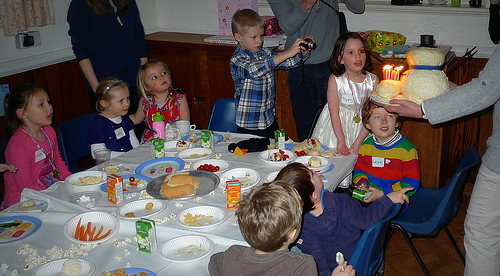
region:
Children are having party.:
[6, 33, 438, 258]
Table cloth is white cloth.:
[55, 163, 242, 260]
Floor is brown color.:
[389, 230, 476, 273]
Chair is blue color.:
[360, 153, 465, 271]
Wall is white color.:
[144, 11, 228, 36]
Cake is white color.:
[376, 37, 453, 108]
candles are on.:
[371, 56, 416, 120]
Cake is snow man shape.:
[402, 23, 464, 105]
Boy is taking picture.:
[226, 16, 321, 129]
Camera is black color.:
[288, 39, 321, 69]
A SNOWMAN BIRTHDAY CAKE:
[368, 29, 481, 119]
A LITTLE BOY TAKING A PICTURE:
[221, 0, 321, 142]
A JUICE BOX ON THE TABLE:
[129, 214, 168, 255]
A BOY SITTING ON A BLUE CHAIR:
[347, 97, 481, 273]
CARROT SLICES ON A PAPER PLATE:
[60, 206, 124, 247]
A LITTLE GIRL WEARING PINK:
[2, 82, 74, 207]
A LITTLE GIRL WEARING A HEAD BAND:
[90, 73, 146, 162]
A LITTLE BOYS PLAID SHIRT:
[223, 42, 298, 137]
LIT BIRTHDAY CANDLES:
[374, 58, 409, 86]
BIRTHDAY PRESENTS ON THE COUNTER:
[198, 2, 296, 52]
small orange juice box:
[225, 179, 242, 211]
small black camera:
[294, 36, 318, 58]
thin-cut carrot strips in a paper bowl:
[63, 211, 120, 243]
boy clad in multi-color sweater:
[348, 97, 423, 204]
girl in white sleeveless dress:
[321, 32, 376, 149]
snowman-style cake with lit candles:
[369, 31, 475, 111]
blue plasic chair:
[392, 157, 477, 239]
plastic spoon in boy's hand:
[332, 250, 354, 275]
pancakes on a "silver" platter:
[144, 172, 216, 196]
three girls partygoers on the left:
[0, 55, 196, 207]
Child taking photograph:
[226, 9, 316, 132]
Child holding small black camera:
[222, 5, 314, 133]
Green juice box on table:
[130, 216, 156, 255]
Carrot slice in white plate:
[87, 219, 105, 244]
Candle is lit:
[382, 55, 392, 83]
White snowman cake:
[371, 25, 454, 115]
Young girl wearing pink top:
[1, 79, 73, 194]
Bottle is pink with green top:
[150, 112, 168, 142]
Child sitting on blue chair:
[348, 97, 418, 207]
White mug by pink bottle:
[167, 116, 197, 133]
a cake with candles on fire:
[376, 48, 429, 112]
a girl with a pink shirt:
[16, 91, 70, 183]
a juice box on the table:
[93, 161, 140, 218]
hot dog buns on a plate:
[152, 167, 219, 205]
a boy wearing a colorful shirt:
[350, 115, 446, 211]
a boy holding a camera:
[291, 30, 328, 66]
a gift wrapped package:
[355, 16, 426, 58]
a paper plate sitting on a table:
[163, 222, 224, 269]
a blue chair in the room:
[403, 168, 465, 267]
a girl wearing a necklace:
[339, 61, 380, 138]